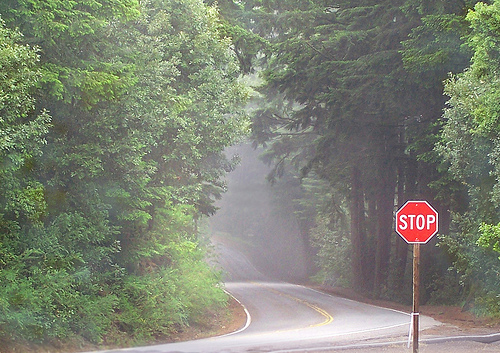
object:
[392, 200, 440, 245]
sign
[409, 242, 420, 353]
pole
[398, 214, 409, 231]
letters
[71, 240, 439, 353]
road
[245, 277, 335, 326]
stripe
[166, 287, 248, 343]
dirt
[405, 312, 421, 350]
ribbon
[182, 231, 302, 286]
foggy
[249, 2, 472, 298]
tree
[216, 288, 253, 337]
line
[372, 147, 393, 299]
trunk